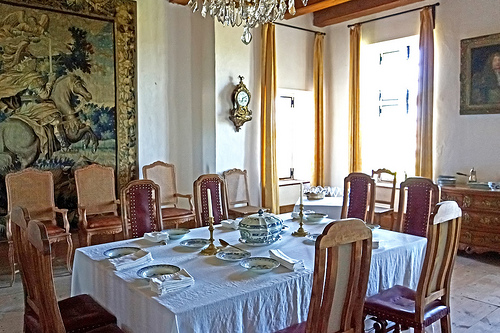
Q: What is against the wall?
A: Wood chairs.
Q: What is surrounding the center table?
A: Chairs.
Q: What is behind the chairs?
A: A large art piece.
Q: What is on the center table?
A: Dishes and plates.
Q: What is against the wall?
A: Three chairs.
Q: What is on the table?
A: A white cloth.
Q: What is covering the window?
A: Yellow curtains.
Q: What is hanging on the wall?
A: A large painting.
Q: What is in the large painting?
A: A horse.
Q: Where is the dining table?
A: In a dining room.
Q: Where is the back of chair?
A: At the dining table.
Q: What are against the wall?
A: Three chairs.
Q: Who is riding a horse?
A: A knight.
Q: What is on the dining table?
A: Dining ware.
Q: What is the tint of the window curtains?
A: Tan.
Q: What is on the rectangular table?
A: White tablecloth.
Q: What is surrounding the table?
A: Wooden chairs.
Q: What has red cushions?
A: Wooden chairs.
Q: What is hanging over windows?
A: Curtains.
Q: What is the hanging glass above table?
A: Chandelier.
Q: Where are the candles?
A: On the table.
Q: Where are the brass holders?
A: On table.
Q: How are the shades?
A: Partially down.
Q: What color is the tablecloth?
A: White.